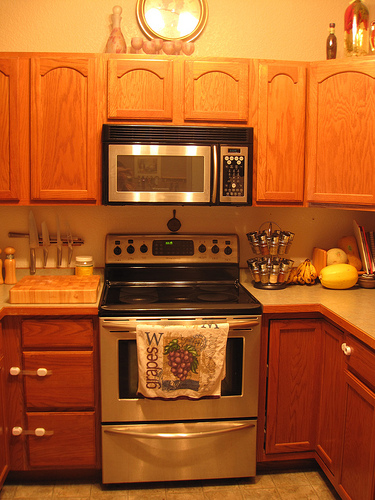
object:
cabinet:
[106, 56, 172, 121]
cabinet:
[183, 57, 248, 121]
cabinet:
[256, 60, 307, 203]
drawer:
[21, 319, 94, 349]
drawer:
[23, 347, 94, 410]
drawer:
[27, 411, 97, 468]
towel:
[133, 321, 229, 399]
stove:
[100, 234, 264, 488]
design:
[145, 331, 206, 392]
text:
[145, 331, 164, 391]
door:
[21, 318, 96, 467]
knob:
[8, 365, 21, 376]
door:
[99, 314, 261, 424]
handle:
[100, 320, 257, 328]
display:
[223, 156, 245, 196]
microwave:
[100, 121, 253, 207]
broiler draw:
[102, 417, 256, 488]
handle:
[106, 423, 254, 438]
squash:
[319, 261, 360, 289]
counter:
[240, 266, 375, 348]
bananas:
[285, 259, 318, 285]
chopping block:
[10, 273, 101, 303]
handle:
[211, 144, 217, 204]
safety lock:
[10, 367, 48, 379]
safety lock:
[12, 426, 44, 437]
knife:
[28, 209, 38, 275]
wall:
[0, 0, 375, 60]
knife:
[42, 217, 50, 267]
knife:
[55, 213, 63, 266]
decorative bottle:
[105, 7, 128, 54]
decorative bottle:
[131, 35, 143, 55]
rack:
[246, 222, 296, 289]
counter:
[0, 266, 105, 316]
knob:
[36, 366, 48, 378]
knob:
[34, 426, 46, 438]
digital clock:
[152, 239, 194, 256]